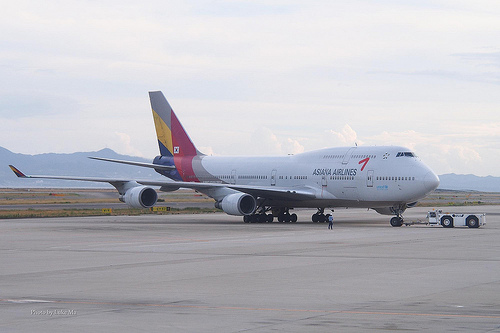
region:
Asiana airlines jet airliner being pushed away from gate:
[7, 90, 489, 230]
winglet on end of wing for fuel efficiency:
[8, 165, 25, 177]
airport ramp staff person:
[325, 208, 334, 227]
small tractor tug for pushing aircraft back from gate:
[403, 211, 486, 228]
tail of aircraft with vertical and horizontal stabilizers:
[88, 92, 209, 177]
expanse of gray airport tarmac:
[0, 205, 498, 331]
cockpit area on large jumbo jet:
[392, 146, 417, 160]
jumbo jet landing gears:
[243, 206, 405, 227]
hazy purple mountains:
[2, 145, 499, 193]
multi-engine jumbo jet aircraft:
[10, 91, 438, 227]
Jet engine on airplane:
[117, 186, 161, 209]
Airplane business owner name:
[302, 166, 365, 179]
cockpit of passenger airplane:
[391, 146, 427, 163]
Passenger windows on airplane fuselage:
[200, 172, 419, 186]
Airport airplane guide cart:
[406, 208, 487, 233]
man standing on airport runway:
[322, 212, 341, 232]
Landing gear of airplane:
[241, 210, 411, 228]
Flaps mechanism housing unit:
[156, 182, 187, 194]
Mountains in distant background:
[2, 144, 498, 193]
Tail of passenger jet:
[144, 86, 199, 159]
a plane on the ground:
[3, 88, 440, 261]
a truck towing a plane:
[381, 200, 491, 233]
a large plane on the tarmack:
[5, 84, 491, 236]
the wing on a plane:
[6, 155, 308, 209]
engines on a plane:
[116, 178, 262, 215]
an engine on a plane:
[213, 188, 258, 220]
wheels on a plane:
[242, 202, 331, 226]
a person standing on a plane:
[323, 212, 338, 229]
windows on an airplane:
[318, 151, 385, 161]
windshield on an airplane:
[392, 145, 417, 162]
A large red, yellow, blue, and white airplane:
[10, 89, 441, 228]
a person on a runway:
[326, 210, 335, 230]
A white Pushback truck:
[401, 208, 488, 228]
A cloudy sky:
[2, 4, 499, 175]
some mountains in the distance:
[0, 147, 499, 192]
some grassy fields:
[0, 185, 495, 217]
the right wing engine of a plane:
[201, 188, 261, 217]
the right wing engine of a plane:
[105, 180, 159, 210]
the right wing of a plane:
[4, 161, 321, 199]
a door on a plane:
[364, 170, 375, 189]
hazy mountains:
[438, 170, 497, 196]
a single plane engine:
[221, 191, 256, 218]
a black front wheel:
[388, 215, 401, 225]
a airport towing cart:
[407, 208, 488, 228]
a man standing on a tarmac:
[323, 214, 336, 230]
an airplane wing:
[4, 159, 310, 216]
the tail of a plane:
[138, 88, 201, 182]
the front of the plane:
[345, 145, 441, 221]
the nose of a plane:
[421, 169, 442, 194]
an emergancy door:
[268, 169, 278, 186]